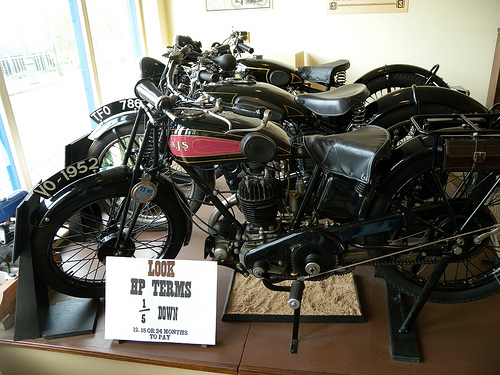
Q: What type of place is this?
A: It is a shop.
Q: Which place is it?
A: It is a shop.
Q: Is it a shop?
A: Yes, it is a shop.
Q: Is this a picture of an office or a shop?
A: It is showing a shop.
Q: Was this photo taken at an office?
A: No, the picture was taken in a shop.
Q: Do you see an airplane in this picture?
A: No, there are no airplanes.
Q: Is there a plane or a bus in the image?
A: No, there are no airplanes or buses.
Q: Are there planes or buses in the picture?
A: No, there are no planes or buses.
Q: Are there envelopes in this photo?
A: No, there are no envelopes.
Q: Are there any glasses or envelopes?
A: No, there are no envelopes or glasses.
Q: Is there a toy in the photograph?
A: No, there are no toys.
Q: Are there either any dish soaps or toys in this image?
A: No, there are no toys or dish soaps.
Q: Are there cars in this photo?
A: No, there are no cars.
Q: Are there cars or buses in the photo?
A: No, there are no cars or buses.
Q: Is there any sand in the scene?
A: Yes, there is sand.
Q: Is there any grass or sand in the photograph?
A: Yes, there is sand.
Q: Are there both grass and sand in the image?
A: No, there is sand but no grass.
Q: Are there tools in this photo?
A: No, there are no tools.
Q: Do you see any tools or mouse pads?
A: No, there are no tools or mouse pads.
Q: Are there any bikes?
A: Yes, there is a bike.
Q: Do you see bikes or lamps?
A: Yes, there is a bike.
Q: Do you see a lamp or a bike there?
A: Yes, there is a bike.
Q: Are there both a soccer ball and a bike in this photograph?
A: No, there is a bike but no soccer balls.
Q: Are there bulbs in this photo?
A: No, there are no bulbs.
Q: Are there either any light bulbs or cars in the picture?
A: No, there are no light bulbs or cars.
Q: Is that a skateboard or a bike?
A: That is a bike.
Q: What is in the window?
A: The bike is in the window.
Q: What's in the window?
A: The bike is in the window.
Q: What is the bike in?
A: The bike is in the window.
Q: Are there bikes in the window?
A: Yes, there is a bike in the window.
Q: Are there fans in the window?
A: No, there is a bike in the window.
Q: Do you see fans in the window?
A: No, there is a bike in the window.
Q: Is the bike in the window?
A: Yes, the bike is in the window.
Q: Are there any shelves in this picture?
A: No, there are no shelves.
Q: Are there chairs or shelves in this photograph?
A: No, there are no shelves or chairs.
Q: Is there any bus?
A: No, there are no buses.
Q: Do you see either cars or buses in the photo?
A: No, there are no buses or cars.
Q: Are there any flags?
A: No, there are no flags.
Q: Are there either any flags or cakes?
A: No, there are no flags or cakes.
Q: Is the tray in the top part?
A: No, the tray is in the bottom of the image.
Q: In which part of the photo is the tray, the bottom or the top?
A: The tray is in the bottom of the image.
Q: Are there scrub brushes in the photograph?
A: No, there are no scrub brushes.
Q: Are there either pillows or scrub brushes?
A: No, there are no scrub brushes or pillows.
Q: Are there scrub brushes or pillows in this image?
A: No, there are no scrub brushes or pillows.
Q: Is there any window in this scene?
A: Yes, there is a window.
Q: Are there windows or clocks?
A: Yes, there is a window.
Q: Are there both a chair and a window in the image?
A: No, there is a window but no chairs.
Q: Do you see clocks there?
A: No, there are no clocks.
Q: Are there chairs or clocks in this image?
A: No, there are no clocks or chairs.